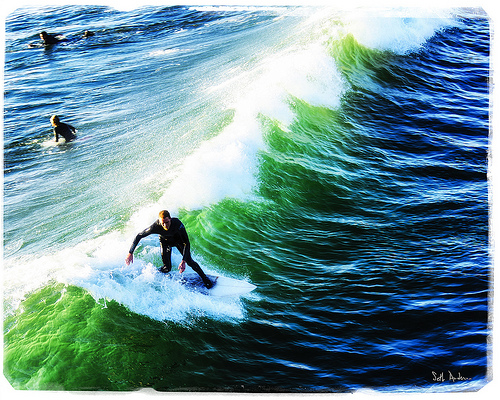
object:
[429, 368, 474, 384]
signature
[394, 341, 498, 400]
corner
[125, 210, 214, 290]
man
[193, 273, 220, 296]
surfboard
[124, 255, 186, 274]
hands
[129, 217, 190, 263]
black suit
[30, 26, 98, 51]
swimmers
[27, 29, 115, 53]
group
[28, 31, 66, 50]
man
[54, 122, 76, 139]
wetsuit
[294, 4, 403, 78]
crest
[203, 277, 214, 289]
blue material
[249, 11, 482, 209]
wave crest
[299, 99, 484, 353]
wave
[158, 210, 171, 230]
head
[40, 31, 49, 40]
head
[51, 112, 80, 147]
person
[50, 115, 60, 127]
head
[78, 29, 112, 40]
person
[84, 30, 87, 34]
head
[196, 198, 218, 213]
there is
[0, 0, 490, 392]
lake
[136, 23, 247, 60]
here is